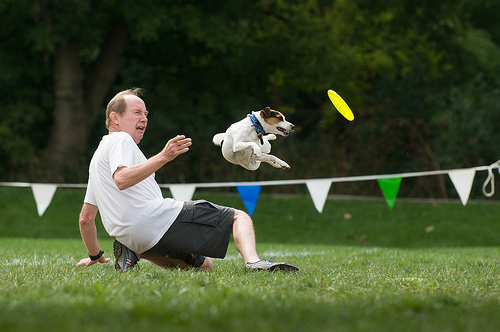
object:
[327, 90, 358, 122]
frisbee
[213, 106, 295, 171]
dog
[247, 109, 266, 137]
collar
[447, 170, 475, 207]
banner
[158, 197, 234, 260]
brown shorts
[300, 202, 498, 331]
grass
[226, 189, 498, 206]
trail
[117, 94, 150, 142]
odd face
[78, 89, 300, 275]
man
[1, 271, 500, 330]
grass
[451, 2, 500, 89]
trees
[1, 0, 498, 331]
park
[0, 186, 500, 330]
field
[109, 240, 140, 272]
sneakers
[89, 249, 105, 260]
watch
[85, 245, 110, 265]
mans wrist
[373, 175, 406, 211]
banner flags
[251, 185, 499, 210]
pathway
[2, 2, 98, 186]
large tree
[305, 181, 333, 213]
flags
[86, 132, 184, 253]
shirt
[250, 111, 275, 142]
dogs neck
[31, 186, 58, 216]
flags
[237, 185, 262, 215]
flag